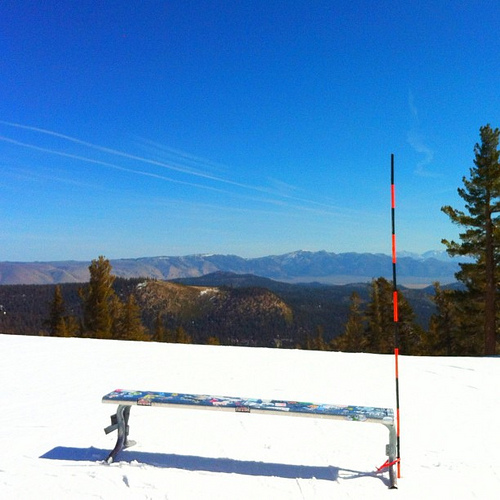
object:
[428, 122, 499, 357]
pine tree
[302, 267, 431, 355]
trees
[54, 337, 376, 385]
snow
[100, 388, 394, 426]
stickers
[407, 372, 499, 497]
snow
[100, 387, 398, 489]
bench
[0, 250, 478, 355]
mountain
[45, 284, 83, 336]
tree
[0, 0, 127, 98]
sky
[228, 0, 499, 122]
sky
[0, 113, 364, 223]
lines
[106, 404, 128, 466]
legs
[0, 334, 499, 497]
snowy mountain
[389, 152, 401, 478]
pole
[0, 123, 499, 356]
forest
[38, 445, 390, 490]
shadow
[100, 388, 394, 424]
seat